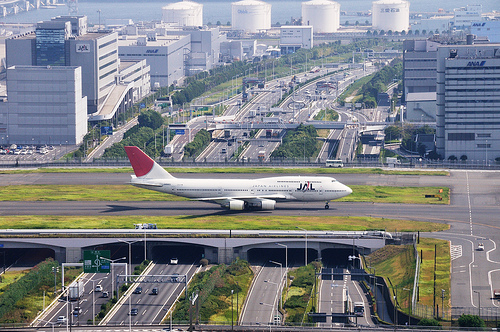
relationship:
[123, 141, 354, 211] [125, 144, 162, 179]
plane has wing tip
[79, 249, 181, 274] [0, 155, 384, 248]
traffic under bridge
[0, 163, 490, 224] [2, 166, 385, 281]
runway above bridge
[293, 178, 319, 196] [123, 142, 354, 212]
logo on plane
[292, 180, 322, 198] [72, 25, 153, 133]
logo on building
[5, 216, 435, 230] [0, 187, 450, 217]
grass around runway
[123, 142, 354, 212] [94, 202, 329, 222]
plane has shadow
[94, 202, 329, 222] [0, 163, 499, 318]
shadow on ground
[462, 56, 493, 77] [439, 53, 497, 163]
logo on building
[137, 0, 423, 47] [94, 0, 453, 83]
structures in background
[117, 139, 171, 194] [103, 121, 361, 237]
tail on plane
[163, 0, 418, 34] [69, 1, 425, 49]
tanks in background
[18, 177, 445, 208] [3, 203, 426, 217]
grass between runway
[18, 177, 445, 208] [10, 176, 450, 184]
grass between runway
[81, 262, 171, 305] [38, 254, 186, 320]
cars on highway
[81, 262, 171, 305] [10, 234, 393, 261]
cars in front of bridge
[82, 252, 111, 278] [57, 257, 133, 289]
sign on pole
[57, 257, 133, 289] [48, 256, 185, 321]
pole above highway